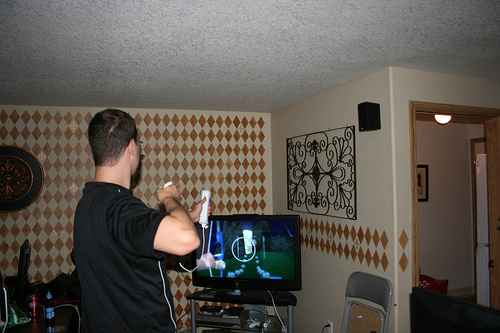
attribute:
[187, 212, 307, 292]
television — on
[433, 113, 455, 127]
light — on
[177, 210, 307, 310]
tv — flat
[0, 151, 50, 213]
black fence — brass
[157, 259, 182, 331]
stripe — white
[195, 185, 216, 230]
remote — wii, Nintendo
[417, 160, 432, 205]
print — art, framed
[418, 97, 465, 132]
light — on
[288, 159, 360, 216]
art — black, metal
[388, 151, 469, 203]
picture — framed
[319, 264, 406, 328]
chair — steel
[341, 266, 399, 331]
chair — grey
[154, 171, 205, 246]
controller — wii controller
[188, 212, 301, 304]
tv — on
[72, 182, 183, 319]
shirt — black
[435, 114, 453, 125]
fixture — light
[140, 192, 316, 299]
television — black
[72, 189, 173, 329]
shirt — black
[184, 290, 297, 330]
stand — black, television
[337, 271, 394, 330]
chair — gray, closed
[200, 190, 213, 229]
remote — white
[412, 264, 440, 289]
container — red, plastic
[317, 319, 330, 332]
cord — plugged in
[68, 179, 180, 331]
shirt — black